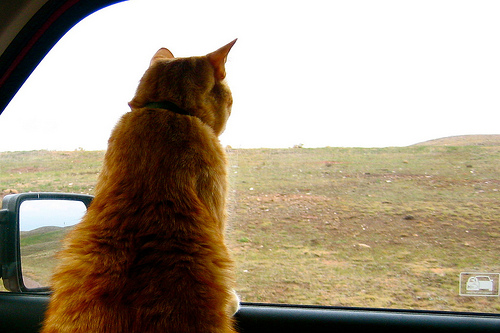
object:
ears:
[148, 38, 239, 81]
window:
[0, 0, 498, 316]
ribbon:
[140, 100, 195, 118]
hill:
[404, 129, 500, 151]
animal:
[133, 88, 182, 116]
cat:
[113, 149, 192, 277]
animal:
[403, 159, 408, 163]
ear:
[208, 37, 239, 82]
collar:
[131, 97, 194, 118]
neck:
[136, 100, 216, 154]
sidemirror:
[0, 191, 19, 295]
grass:
[250, 158, 499, 213]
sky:
[0, 0, 499, 153]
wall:
[224, 108, 306, 159]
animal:
[40, 36, 241, 333]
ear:
[149, 47, 174, 66]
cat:
[39, 36, 240, 333]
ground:
[1, 133, 500, 313]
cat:
[96, 167, 206, 303]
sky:
[398, 49, 446, 97]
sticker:
[459, 272, 500, 298]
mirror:
[0, 191, 97, 295]